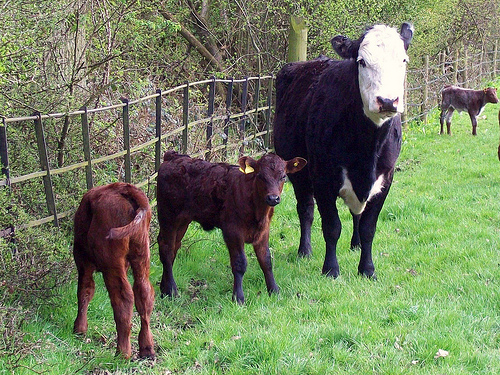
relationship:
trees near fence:
[1, 1, 498, 217] [0, 35, 498, 295]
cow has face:
[260, 18, 417, 286] [355, 32, 412, 121]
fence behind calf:
[0, 35, 498, 295] [150, 151, 310, 307]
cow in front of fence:
[260, 18, 417, 286] [0, 35, 498, 295]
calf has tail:
[63, 181, 161, 363] [102, 187, 153, 245]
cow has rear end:
[63, 181, 161, 363] [95, 194, 155, 264]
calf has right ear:
[150, 151, 310, 307] [236, 153, 264, 174]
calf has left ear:
[150, 151, 310, 307] [282, 153, 309, 176]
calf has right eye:
[150, 151, 310, 307] [256, 170, 266, 180]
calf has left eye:
[150, 151, 310, 307] [279, 171, 289, 181]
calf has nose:
[150, 151, 310, 307] [263, 194, 282, 206]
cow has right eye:
[260, 18, 417, 286] [356, 55, 368, 72]